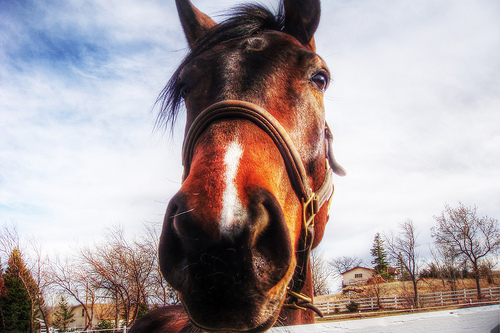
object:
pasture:
[0, 275, 500, 332]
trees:
[1, 246, 47, 332]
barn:
[37, 317, 133, 332]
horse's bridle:
[177, 97, 334, 252]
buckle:
[301, 187, 319, 237]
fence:
[318, 287, 500, 316]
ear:
[176, 1, 219, 46]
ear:
[276, 0, 323, 40]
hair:
[155, 2, 276, 127]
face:
[145, 2, 350, 322]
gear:
[174, 94, 339, 235]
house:
[341, 262, 381, 291]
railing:
[314, 286, 500, 321]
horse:
[110, 1, 351, 332]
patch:
[213, 137, 246, 237]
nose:
[157, 187, 294, 298]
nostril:
[251, 188, 297, 291]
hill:
[0, 278, 500, 328]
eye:
[308, 68, 328, 92]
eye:
[173, 82, 191, 103]